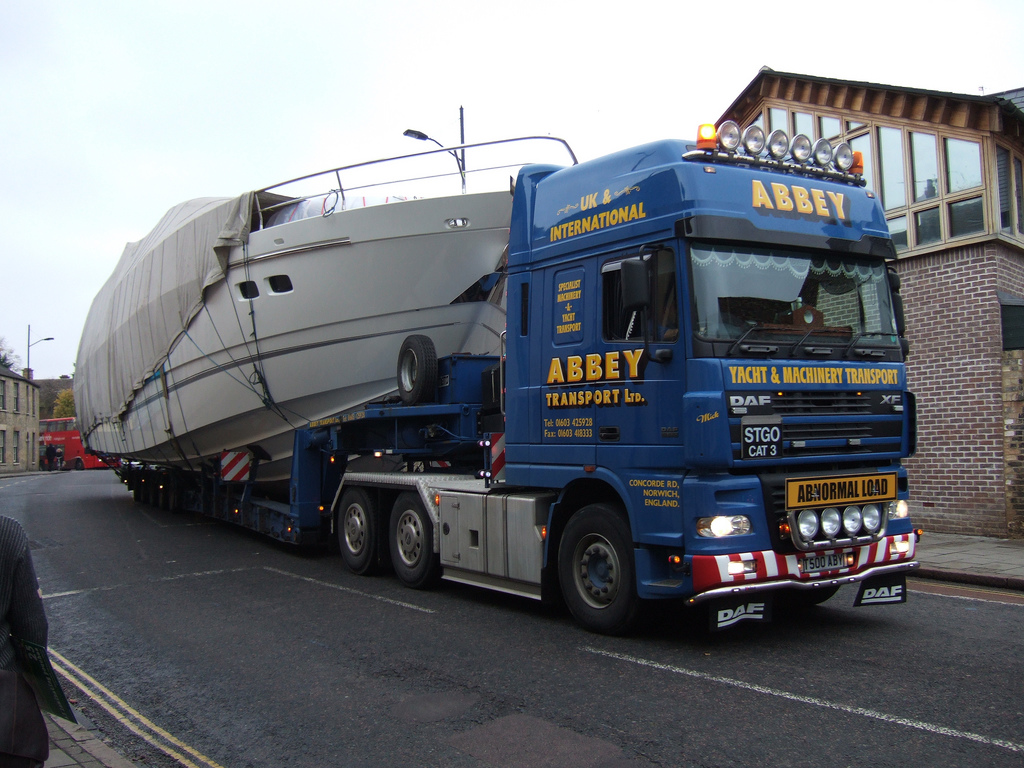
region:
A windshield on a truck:
[682, 231, 905, 365]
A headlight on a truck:
[697, 504, 758, 547]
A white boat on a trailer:
[72, 133, 578, 466]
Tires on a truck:
[553, 493, 642, 630]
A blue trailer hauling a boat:
[104, 361, 501, 545]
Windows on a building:
[875, 118, 987, 249]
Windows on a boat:
[229, 272, 305, 308]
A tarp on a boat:
[66, 187, 294, 440]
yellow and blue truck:
[317, 115, 930, 633]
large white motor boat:
[61, 127, 577, 469]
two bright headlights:
[694, 487, 917, 539]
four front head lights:
[791, 497, 880, 535]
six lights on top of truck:
[708, 112, 857, 170]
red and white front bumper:
[669, 525, 929, 608]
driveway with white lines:
[0, 460, 1023, 759]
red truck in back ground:
[20, 406, 110, 470]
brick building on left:
[0, 358, 45, 476]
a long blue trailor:
[84, 349, 497, 553]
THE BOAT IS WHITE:
[42, 147, 594, 473]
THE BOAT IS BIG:
[49, 102, 593, 477]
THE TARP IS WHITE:
[52, 166, 318, 446]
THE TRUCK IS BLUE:
[77, 141, 931, 654]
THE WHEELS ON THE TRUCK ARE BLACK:
[296, 462, 636, 662]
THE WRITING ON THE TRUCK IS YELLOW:
[523, 339, 675, 419]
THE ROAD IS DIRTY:
[8, 463, 1007, 767]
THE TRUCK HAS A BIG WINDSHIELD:
[648, 204, 923, 385]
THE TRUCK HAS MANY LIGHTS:
[693, 485, 928, 549]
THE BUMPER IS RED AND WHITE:
[693, 530, 932, 617]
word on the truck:
[753, 161, 853, 215]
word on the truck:
[629, 478, 691, 511]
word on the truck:
[579, 186, 633, 207]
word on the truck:
[544, 277, 580, 298]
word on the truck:
[542, 304, 577, 331]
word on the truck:
[538, 341, 611, 374]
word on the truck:
[548, 394, 616, 414]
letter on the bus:
[740, 179, 783, 214]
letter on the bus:
[765, 357, 789, 386]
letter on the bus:
[882, 363, 901, 383]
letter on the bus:
[610, 382, 642, 406]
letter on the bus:
[592, 354, 619, 386]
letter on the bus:
[560, 353, 587, 369]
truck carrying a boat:
[76, 81, 982, 648]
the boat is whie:
[54, 78, 533, 474]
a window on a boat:
[234, 279, 257, 296]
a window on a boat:
[265, 275, 298, 296]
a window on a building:
[876, 130, 905, 210]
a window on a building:
[906, 125, 942, 192]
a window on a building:
[942, 134, 980, 191]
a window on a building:
[947, 196, 987, 226]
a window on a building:
[912, 210, 938, 245]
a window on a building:
[882, 209, 915, 251]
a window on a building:
[849, 134, 870, 186]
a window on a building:
[817, 115, 844, 134]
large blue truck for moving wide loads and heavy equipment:
[501, 146, 931, 641]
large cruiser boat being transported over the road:
[40, 133, 559, 479]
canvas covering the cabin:
[57, 164, 295, 440]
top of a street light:
[401, 107, 491, 177]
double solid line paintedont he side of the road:
[53, 644, 203, 766]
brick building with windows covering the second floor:
[711, 43, 1018, 543]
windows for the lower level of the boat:
[239, 261, 300, 326]